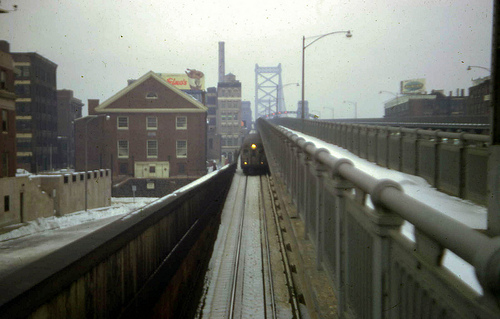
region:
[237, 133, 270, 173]
the train on the tracks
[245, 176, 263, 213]
snow on the tracks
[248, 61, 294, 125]
the bridge in the background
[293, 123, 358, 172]
snow on the walkway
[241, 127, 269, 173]
train beside the walkway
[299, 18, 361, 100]
the street light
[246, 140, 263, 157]
light on the train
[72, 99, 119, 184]
street light over the street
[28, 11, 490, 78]
the sky is gray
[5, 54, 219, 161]
the buildings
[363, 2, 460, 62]
this is the sky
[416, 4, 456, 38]
the sky is blue in color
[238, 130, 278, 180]
this is a train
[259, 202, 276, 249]
this is a metal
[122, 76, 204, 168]
this is a building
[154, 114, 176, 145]
this is the wall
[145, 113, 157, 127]
this is the window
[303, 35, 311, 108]
this is a pole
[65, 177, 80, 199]
the wall is brown in color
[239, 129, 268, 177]
Train on the thin tracks.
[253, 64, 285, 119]
Metal frame bridge in the distance.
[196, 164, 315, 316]
Thin strip where the train comes down the track.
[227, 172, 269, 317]
Train track in front of a train.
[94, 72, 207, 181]
A brick building with white frame and 6 larger windows.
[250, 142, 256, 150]
Top round illuminated light on a train top.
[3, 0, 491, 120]
Hazy white sky.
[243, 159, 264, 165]
Two smaller bottom lights on a train.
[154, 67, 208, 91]
A billboard with a drink spilling and red writing.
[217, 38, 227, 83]
A tall smoke stack sticking up past the train.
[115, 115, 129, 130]
glass window of building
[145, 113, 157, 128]
glass window of building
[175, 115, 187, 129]
glass window of building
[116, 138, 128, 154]
glass window of building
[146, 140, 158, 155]
glass window of building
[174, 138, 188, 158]
glass window of building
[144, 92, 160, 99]
glass window of building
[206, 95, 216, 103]
glass window of building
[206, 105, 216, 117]
glass window of building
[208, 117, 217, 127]
glass window of building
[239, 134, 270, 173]
A train on a track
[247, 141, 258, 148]
A light on a train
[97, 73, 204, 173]
A brick building near a train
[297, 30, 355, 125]
A street light near a train track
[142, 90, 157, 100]
A half circle window on a building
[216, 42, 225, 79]
A smokestack on a building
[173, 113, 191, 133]
A window on a brick building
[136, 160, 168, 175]
A door on a building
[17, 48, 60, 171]
A tall building in a city